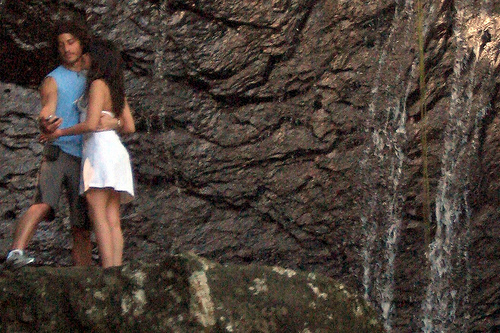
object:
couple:
[0, 20, 146, 277]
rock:
[1, 254, 380, 333]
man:
[0, 22, 124, 265]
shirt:
[40, 64, 83, 157]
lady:
[36, 38, 143, 277]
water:
[354, 4, 491, 333]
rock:
[327, 1, 500, 333]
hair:
[81, 38, 134, 120]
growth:
[412, 5, 431, 255]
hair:
[47, 25, 88, 50]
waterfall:
[354, 1, 492, 332]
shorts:
[32, 146, 89, 227]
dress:
[76, 96, 139, 207]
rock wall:
[1, 1, 500, 333]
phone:
[42, 113, 62, 123]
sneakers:
[2, 250, 39, 268]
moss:
[1, 260, 383, 333]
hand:
[35, 115, 62, 135]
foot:
[0, 247, 40, 269]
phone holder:
[41, 144, 61, 161]